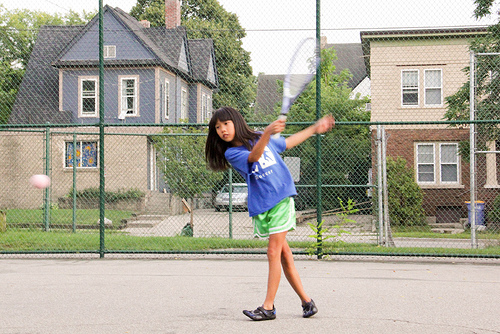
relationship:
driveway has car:
[182, 203, 231, 233] [218, 177, 252, 214]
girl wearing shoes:
[200, 96, 342, 327] [244, 296, 332, 326]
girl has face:
[200, 96, 342, 327] [213, 111, 241, 145]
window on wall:
[81, 74, 96, 118] [64, 64, 79, 102]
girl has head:
[200, 96, 342, 327] [204, 103, 246, 131]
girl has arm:
[200, 96, 342, 327] [227, 134, 279, 172]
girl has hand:
[200, 96, 342, 327] [268, 109, 291, 137]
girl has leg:
[200, 96, 342, 327] [254, 230, 295, 289]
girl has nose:
[200, 96, 342, 327] [218, 124, 229, 132]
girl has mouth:
[200, 96, 342, 327] [217, 132, 234, 142]